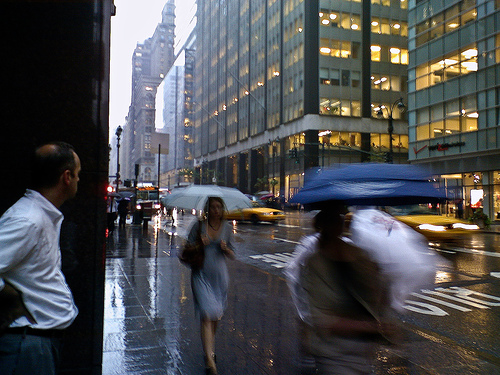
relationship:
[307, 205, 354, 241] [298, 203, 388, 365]
head of person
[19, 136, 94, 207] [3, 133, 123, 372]
head of person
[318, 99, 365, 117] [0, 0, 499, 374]
window of building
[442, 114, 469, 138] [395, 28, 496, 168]
window on building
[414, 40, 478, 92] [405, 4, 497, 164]
glass window attached to building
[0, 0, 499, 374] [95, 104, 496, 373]
building near street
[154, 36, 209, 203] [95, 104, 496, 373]
building near street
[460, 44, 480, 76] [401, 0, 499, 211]
glass window on building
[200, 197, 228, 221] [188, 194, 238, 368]
head of person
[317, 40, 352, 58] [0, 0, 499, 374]
window of building